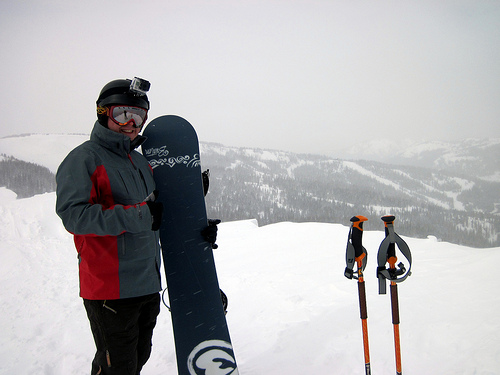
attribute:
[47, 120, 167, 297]
coat — red, gray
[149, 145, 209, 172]
sign — white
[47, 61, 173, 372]
person —  posing